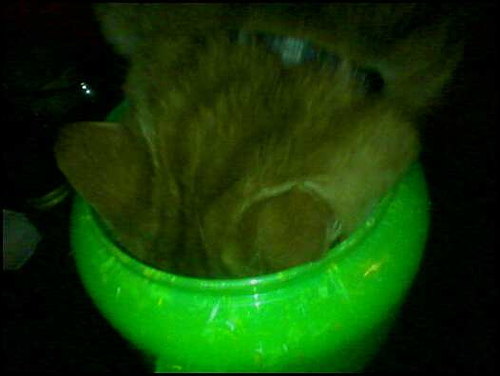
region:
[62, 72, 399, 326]
cat is eating in the jar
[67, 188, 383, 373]
the jar is green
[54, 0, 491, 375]
Cat with face in bowl.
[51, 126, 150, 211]
The cat's left ear.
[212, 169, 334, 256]
The right ear of the cat.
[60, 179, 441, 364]
The green bowl the cat's face is in.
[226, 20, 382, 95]
The collar on the cat.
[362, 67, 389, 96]
The black clip on the collar on the right.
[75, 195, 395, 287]
The rim of the green vase.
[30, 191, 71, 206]
The gold lid on the jar on the left.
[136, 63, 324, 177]
The back of the cat's head.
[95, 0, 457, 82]
The top of the cat's body.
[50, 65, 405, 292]
a cat eating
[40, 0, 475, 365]
a cat in a green bowl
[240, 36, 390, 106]
a cats silver collar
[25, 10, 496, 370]
a yellow cat eating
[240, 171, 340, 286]
a left cat ear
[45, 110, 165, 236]
a right cat ear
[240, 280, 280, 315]
reflection on a bowl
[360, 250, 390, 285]
a small flake of green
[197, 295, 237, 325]
a white flake of white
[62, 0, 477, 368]
a yellow cat in a green bowl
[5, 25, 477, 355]
a cat and a green bowl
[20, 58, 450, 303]
a cat eating out of a green bowl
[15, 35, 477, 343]
a cat with its head in a bowl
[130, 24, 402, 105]
a collar on a cat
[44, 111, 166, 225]
an ear on a cat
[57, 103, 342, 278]
cat ears sticking out of a bowl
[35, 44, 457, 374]
a cat eating out of a green dish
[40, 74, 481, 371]
a cat eating out of a green bot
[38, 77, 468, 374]
a cat's head in a dish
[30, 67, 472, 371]
a cat's head in a pot